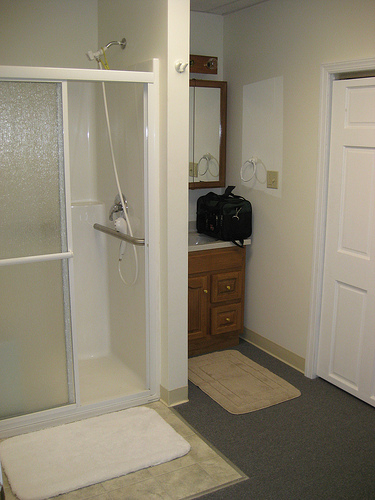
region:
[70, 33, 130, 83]
white shower head above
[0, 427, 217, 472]
white colored bath rug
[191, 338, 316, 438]
tan colored bath tub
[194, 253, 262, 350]
brown wooden bathroom cabinets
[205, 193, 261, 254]
black duffle bag on counter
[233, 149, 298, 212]
towel circle white rod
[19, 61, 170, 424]
white frame around bathroom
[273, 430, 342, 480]
gray slate tile floor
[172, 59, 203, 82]
small white hook for hanging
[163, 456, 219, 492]
tan colored bathroom tile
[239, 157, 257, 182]
a round, white towel hanger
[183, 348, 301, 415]
a rectangular carpet mat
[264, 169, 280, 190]
a square tan light switch panel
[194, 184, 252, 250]
a black bag sitting by the sink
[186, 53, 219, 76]
light bulbs in a brown wooden fixture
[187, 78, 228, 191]
a mirror with a brown wooden border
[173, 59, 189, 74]
a white towel hanger with two hooks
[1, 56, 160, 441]
a large white shower with a sliding door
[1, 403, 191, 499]
a white fluffy looking bath mat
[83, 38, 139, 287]
a white movable shower head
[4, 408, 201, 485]
white bathroom mat on the floor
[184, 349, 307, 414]
beige carpeted mat on carpet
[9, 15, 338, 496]
white shower in bathroom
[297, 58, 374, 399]
white bathroom door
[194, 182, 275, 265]
black bag sitting on sink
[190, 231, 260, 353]
brown and white sink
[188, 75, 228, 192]
mirror on wall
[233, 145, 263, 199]
white towel round rack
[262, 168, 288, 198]
light switch for bathroom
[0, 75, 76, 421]
sliding door for shower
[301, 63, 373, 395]
white door of a bathroom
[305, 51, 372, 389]
frame of door is white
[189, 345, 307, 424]
a rug in front a sink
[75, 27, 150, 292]
the shower of a bathroom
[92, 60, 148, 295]
long tube of a shower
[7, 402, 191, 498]
a white rug in front a shower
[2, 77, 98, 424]
door of shower is glass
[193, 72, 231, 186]
a mirror in front a sink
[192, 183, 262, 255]
a black bag on a sink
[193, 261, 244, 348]
cabinets under a sink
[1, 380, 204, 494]
Fluffy white carpet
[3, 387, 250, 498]
Tan ceramic tiles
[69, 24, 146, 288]
Shower head with attachment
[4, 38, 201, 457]
Shower stall with sliding doors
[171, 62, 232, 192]
Medicine cabinet with mirrored front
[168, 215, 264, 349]
Medium brown wooden bathroom cabinet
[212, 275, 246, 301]
Drawer with round gold knob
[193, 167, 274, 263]
Black duffel bag on counter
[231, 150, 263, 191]
Circular towel rack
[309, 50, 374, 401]
Six panel white door